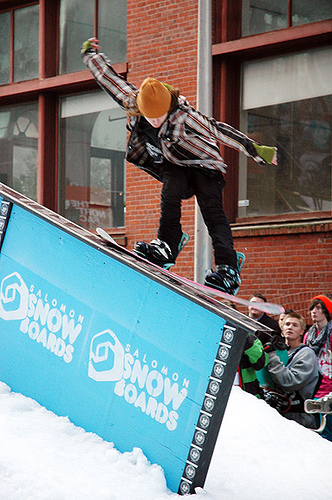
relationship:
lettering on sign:
[107, 341, 190, 432] [2, 184, 245, 499]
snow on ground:
[2, 381, 166, 496] [3, 365, 329, 497]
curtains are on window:
[240, 48, 329, 110] [228, 0, 331, 226]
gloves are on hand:
[77, 30, 101, 60] [80, 36, 101, 57]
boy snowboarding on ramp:
[80, 34, 244, 294] [94, 220, 288, 318]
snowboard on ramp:
[87, 219, 288, 325] [2, 180, 248, 498]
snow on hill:
[3, 373, 331, 495] [0, 347, 328, 495]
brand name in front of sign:
[85, 327, 193, 426] [26, 257, 201, 496]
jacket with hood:
[119, 121, 225, 181] [167, 85, 195, 128]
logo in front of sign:
[81, 324, 127, 386] [38, 255, 235, 498]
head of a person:
[121, 72, 184, 146] [91, 53, 237, 266]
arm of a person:
[77, 50, 131, 109] [81, 33, 274, 302]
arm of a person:
[201, 112, 250, 159] [81, 33, 274, 302]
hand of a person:
[80, 36, 99, 57] [78, 18, 287, 325]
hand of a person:
[253, 141, 282, 173] [78, 18, 287, 325]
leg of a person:
[154, 179, 187, 246] [85, 25, 291, 311]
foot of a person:
[136, 230, 176, 266] [81, 33, 274, 302]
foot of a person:
[205, 258, 242, 297] [85, 25, 291, 311]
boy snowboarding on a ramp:
[80, 34, 278, 294] [67, 221, 300, 390]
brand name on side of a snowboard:
[87, 330, 192, 434] [73, 230, 249, 474]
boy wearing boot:
[80, 34, 278, 294] [126, 212, 200, 283]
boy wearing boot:
[80, 34, 278, 294] [206, 245, 240, 300]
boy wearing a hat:
[80, 34, 278, 294] [133, 73, 177, 123]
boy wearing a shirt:
[80, 34, 278, 294] [163, 114, 227, 179]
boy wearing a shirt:
[80, 34, 278, 294] [131, 121, 181, 173]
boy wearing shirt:
[80, 34, 278, 294] [142, 127, 181, 175]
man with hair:
[261, 301, 325, 377] [283, 310, 302, 323]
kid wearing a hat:
[302, 293, 332, 427] [315, 295, 330, 308]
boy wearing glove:
[80, 34, 278, 294] [255, 140, 274, 165]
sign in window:
[55, 179, 117, 232] [46, 76, 163, 273]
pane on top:
[9, 0, 41, 80] [4, 2, 134, 70]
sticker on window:
[237, 195, 250, 209] [225, 52, 331, 214]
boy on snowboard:
[80, 34, 278, 294] [91, 223, 288, 319]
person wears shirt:
[230, 290, 279, 396] [232, 288, 279, 402]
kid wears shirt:
[297, 289, 330, 427] [301, 323, 329, 354]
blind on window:
[55, 90, 125, 122] [50, 90, 128, 233]